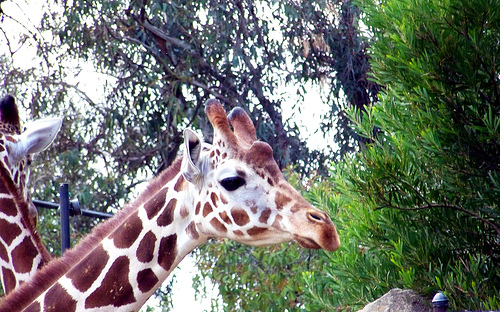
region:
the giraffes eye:
[207, 165, 247, 193]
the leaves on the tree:
[345, 164, 427, 256]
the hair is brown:
[66, 242, 84, 259]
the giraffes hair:
[33, 264, 48, 284]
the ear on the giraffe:
[177, 123, 205, 170]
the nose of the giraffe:
[304, 205, 325, 227]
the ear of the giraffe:
[22, 117, 65, 151]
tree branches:
[152, 27, 202, 73]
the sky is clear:
[293, 97, 325, 133]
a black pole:
[30, 166, 90, 236]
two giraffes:
[0, 91, 335, 308]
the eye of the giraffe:
[215, 166, 241, 186]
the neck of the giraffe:
[51, 200, 198, 286]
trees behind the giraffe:
[205, 35, 450, 125]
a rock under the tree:
[357, 285, 437, 310]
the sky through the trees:
[11, 6, 381, 87]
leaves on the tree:
[357, 10, 487, 275]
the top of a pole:
[426, 290, 459, 310]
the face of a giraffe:
[174, 111, 337, 264]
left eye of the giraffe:
[211, 173, 247, 193]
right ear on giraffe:
[175, 119, 205, 186]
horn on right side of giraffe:
[203, 95, 234, 139]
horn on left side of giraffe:
[230, 109, 258, 143]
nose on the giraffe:
[308, 204, 325, 227]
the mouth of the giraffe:
[293, 228, 334, 251]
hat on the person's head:
[427, 285, 448, 306]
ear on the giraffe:
[26, 112, 68, 151]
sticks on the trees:
[400, 188, 478, 227]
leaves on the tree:
[347, 58, 444, 179]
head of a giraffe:
[159, 88, 341, 261]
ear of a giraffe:
[162, 111, 217, 174]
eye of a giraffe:
[213, 162, 248, 196]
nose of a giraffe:
[302, 200, 329, 233]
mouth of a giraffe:
[254, 216, 354, 266]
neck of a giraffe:
[102, 163, 199, 296]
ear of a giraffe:
[25, 105, 75, 162]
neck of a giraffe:
[0, 180, 63, 247]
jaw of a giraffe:
[205, 225, 330, 262]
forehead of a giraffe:
[232, 139, 296, 188]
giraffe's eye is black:
[206, 161, 249, 199]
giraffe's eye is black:
[210, 170, 267, 209]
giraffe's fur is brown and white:
[60, 143, 155, 293]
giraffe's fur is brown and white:
[5, 174, 178, 309]